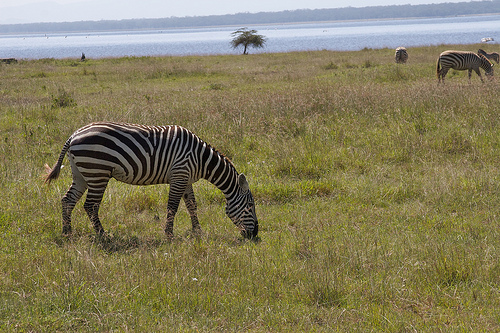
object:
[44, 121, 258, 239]
zebra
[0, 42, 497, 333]
field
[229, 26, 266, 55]
tree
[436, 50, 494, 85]
zebras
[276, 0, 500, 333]
right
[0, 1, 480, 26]
sky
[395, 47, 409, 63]
herd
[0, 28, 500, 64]
shore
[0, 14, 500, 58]
water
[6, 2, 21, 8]
sun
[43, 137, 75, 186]
tail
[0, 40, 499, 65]
beach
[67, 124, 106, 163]
butt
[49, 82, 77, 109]
bush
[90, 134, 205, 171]
striped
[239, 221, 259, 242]
eating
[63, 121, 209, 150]
back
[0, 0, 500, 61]
background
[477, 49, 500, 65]
zebra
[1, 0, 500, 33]
land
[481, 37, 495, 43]
traps